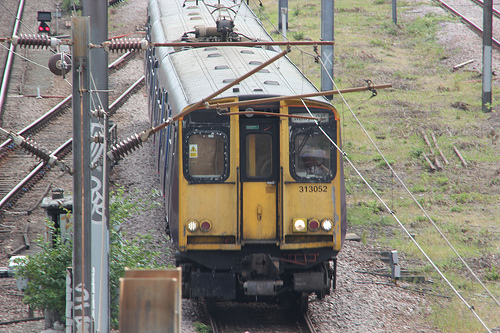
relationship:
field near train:
[340, 5, 499, 327] [151, 1, 343, 325]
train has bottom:
[151, 1, 343, 325] [185, 251, 336, 297]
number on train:
[298, 186, 329, 193] [151, 1, 343, 325]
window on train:
[294, 133, 331, 183] [151, 1, 343, 325]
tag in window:
[191, 144, 196, 159] [188, 135, 226, 177]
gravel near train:
[311, 297, 431, 328] [151, 1, 343, 325]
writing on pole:
[89, 121, 106, 225] [83, 1, 108, 332]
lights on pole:
[40, 25, 51, 34] [83, 1, 108, 332]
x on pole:
[322, 52, 332, 68] [320, 2, 334, 94]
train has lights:
[151, 1, 343, 325] [190, 217, 333, 233]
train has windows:
[151, 1, 343, 325] [184, 135, 334, 180]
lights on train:
[40, 25, 51, 34] [151, 1, 343, 325]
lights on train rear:
[40, 25, 51, 34] [187, 111, 341, 242]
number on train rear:
[298, 186, 329, 193] [187, 111, 341, 242]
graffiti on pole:
[89, 121, 106, 225] [83, 1, 108, 332]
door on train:
[240, 133, 277, 236] [151, 1, 343, 325]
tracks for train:
[196, 299, 316, 331] [151, 1, 343, 325]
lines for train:
[283, 53, 499, 328] [151, 1, 343, 325]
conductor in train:
[300, 144, 331, 177] [151, 1, 343, 325]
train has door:
[151, 1, 343, 325] [240, 133, 277, 236]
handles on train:
[236, 166, 287, 239] [151, 1, 343, 325]